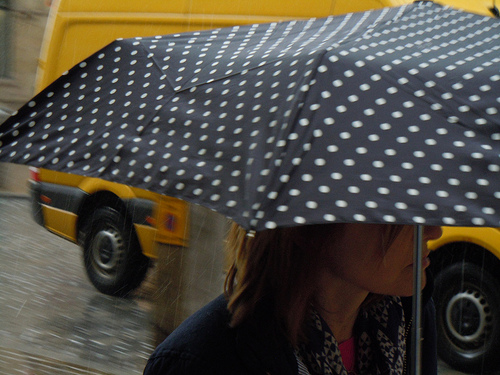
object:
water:
[2, 195, 161, 375]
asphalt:
[0, 159, 175, 373]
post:
[408, 226, 425, 374]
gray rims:
[151, 200, 251, 337]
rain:
[0, 103, 499, 374]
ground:
[0, 192, 174, 374]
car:
[30, 0, 500, 375]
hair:
[214, 217, 411, 356]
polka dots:
[0, 0, 499, 233]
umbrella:
[10, 2, 499, 375]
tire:
[75, 202, 155, 299]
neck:
[306, 266, 371, 343]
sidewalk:
[0, 338, 152, 374]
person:
[141, 222, 441, 374]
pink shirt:
[334, 340, 363, 375]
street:
[0, 0, 500, 374]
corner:
[0, 349, 113, 374]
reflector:
[25, 162, 42, 191]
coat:
[141, 274, 440, 375]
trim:
[33, 175, 158, 226]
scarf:
[289, 277, 409, 375]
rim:
[86, 224, 127, 276]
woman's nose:
[424, 227, 442, 241]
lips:
[404, 252, 430, 271]